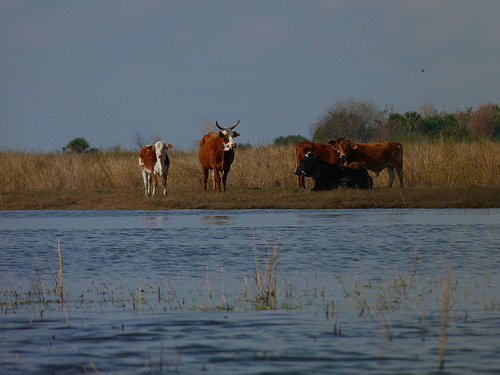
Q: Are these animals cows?
A: Yes, all the animals are cows.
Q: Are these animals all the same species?
A: Yes, all the animals are cows.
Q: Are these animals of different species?
A: No, all the animals are cows.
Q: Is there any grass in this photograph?
A: Yes, there is grass.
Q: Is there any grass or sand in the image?
A: Yes, there is grass.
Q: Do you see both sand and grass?
A: No, there is grass but no sand.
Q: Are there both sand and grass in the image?
A: No, there is grass but no sand.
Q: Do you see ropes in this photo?
A: No, there are no ropes.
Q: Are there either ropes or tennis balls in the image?
A: No, there are no ropes or tennis balls.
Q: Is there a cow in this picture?
A: Yes, there is a cow.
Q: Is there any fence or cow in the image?
A: Yes, there is a cow.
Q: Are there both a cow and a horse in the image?
A: No, there is a cow but no horses.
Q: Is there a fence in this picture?
A: No, there are no fences.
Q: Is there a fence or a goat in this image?
A: No, there are no fences or goats.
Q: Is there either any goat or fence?
A: No, there are no fences or goats.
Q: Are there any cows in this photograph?
A: Yes, there is a cow.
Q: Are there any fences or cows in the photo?
A: Yes, there is a cow.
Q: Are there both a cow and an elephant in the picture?
A: No, there is a cow but no elephants.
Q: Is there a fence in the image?
A: No, there are no fences.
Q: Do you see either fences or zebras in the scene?
A: No, there are no fences or zebras.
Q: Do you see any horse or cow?
A: Yes, there is a cow.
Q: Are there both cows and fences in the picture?
A: No, there is a cow but no fences.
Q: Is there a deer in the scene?
A: No, there is no deer.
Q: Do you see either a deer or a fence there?
A: No, there are no deer or fences.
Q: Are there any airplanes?
A: Yes, there is an airplane.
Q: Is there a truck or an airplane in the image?
A: Yes, there is an airplane.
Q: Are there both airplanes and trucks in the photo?
A: No, there is an airplane but no trucks.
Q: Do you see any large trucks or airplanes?
A: Yes, there is a large airplane.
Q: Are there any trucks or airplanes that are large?
A: Yes, the airplane is large.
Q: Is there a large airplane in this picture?
A: Yes, there is a large airplane.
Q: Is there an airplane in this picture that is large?
A: Yes, there is an airplane that is large.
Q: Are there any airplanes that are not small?
A: Yes, there is a large airplane.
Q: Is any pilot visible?
A: No, there are no pilots.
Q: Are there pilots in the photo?
A: No, there are no pilots.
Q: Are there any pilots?
A: No, there are no pilots.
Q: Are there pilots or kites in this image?
A: No, there are no pilots or kites.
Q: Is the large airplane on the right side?
A: Yes, the plane is on the right of the image.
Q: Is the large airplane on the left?
A: No, the airplane is on the right of the image.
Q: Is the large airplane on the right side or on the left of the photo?
A: The plane is on the right of the image.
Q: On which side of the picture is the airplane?
A: The airplane is on the right of the image.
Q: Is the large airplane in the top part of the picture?
A: Yes, the airplane is in the top of the image.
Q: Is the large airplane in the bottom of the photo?
A: No, the plane is in the top of the image.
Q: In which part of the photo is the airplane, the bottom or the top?
A: The airplane is in the top of the image.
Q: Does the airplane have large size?
A: Yes, the airplane is large.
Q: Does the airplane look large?
A: Yes, the airplane is large.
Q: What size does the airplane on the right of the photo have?
A: The plane has large size.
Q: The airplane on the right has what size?
A: The plane is large.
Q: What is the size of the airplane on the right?
A: The plane is large.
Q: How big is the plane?
A: The plane is large.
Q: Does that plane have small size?
A: No, the plane is large.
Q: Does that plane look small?
A: No, the plane is large.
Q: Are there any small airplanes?
A: No, there is an airplane but it is large.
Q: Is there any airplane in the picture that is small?
A: No, there is an airplane but it is large.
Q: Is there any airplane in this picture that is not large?
A: No, there is an airplane but it is large.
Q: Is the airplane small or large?
A: The airplane is large.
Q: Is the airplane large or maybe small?
A: The airplane is large.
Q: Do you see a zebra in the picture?
A: No, there are no zebras.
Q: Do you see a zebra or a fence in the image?
A: No, there are no zebras or fences.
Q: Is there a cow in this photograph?
A: Yes, there is a cow.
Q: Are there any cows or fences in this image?
A: Yes, there is a cow.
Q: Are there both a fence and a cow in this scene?
A: No, there is a cow but no fences.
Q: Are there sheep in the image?
A: No, there are no sheep.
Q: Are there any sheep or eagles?
A: No, there are no sheep or eagles.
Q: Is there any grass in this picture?
A: Yes, there is grass.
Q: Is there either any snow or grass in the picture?
A: Yes, there is grass.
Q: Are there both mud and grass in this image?
A: No, there is grass but no mud.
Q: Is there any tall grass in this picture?
A: Yes, there is tall grass.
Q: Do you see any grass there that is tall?
A: Yes, there is grass that is tall.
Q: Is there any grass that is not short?
A: Yes, there is tall grass.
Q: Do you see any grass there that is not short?
A: Yes, there is tall grass.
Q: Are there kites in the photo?
A: No, there are no kites.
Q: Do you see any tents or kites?
A: No, there are no kites or tents.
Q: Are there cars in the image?
A: No, there are no cars.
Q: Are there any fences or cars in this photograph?
A: No, there are no cars or fences.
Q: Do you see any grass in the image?
A: Yes, there is grass.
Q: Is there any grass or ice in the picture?
A: Yes, there is grass.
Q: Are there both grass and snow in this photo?
A: No, there is grass but no snow.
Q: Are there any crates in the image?
A: No, there are no crates.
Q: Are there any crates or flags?
A: No, there are no crates or flags.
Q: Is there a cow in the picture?
A: Yes, there are cows.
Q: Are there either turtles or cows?
A: Yes, there are cows.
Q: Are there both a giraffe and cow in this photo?
A: No, there are cows but no giraffes.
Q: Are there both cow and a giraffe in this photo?
A: No, there are cows but no giraffes.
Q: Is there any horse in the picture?
A: No, there are no horses.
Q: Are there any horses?
A: No, there are no horses.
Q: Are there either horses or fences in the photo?
A: No, there are no horses or fences.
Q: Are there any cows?
A: Yes, there is a cow.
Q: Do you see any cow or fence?
A: Yes, there is a cow.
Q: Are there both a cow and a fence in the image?
A: No, there is a cow but no fences.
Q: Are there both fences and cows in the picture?
A: No, there is a cow but no fences.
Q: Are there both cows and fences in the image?
A: No, there is a cow but no fences.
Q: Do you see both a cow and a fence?
A: No, there is a cow but no fences.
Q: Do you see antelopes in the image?
A: No, there are no antelopes.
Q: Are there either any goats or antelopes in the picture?
A: No, there are no antelopes or goats.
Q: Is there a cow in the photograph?
A: Yes, there is a cow.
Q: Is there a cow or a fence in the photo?
A: Yes, there is a cow.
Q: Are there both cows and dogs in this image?
A: No, there is a cow but no dogs.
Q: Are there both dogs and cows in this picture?
A: No, there is a cow but no dogs.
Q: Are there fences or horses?
A: No, there are no fences or horses.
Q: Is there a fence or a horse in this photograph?
A: No, there are no fences or horses.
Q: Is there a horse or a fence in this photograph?
A: No, there are no fences or horses.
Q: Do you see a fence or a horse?
A: No, there are no fences or horses.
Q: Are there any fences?
A: No, there are no fences.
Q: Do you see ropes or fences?
A: No, there are no fences or ropes.